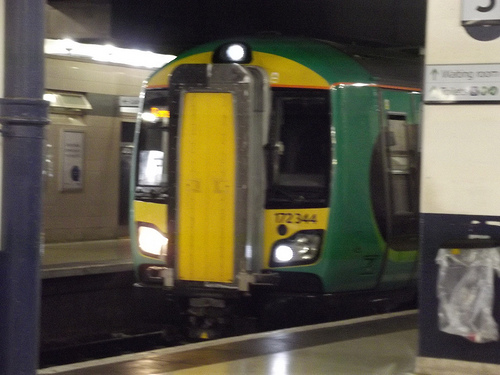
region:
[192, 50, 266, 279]
front yellow door to rain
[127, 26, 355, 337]
yellow and green train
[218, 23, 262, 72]
front light on top of train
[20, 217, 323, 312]
lights on bottom of train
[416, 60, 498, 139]
direction map with arrows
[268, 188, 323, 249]
numbers on bottom of train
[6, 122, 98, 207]
informational poster on wall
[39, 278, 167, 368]
train tracks beneath train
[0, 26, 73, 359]
blue metal pole by train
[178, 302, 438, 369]
platform by train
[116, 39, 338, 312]
front of train car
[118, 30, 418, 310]
green and white train car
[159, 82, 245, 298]
door on the car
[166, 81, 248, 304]
yellow door on the car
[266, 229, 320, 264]
headlight of the train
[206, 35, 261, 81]
top headlight of the train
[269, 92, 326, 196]
windshield of the train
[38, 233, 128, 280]
platform at the train station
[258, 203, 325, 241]
unique number of the car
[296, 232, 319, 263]
headlight in the off status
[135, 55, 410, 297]
subway train on the tracks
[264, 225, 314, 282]
light on the train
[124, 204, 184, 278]
light on the train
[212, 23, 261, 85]
light on the train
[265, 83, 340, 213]
window on the train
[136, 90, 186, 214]
window on the train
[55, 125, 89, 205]
sign on the wall near the train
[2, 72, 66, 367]
post near the train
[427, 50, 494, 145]
sign on the wall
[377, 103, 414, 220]
window on the train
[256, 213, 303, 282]
Light on back of train.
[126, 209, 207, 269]
Light on back of train.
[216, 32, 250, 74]
Light on back of train.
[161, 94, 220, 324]
Yellow door on back of train.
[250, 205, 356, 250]
Black numbers on back of train.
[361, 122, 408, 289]
Ladder on side of train.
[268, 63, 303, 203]
Window on back of train.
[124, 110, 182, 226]
Window on back of train.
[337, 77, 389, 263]
Train is green on side.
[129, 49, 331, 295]
Back of train is yellow.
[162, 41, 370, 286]
green yellow and gray passenger train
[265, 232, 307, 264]
white light on passenger train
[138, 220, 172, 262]
white light on passenger train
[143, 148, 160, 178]
white light on passenger train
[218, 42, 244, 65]
white light on passenger train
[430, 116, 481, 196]
tan wall in train station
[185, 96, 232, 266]
yellow door on passenger train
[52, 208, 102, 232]
tan wall in train station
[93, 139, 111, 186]
tan wall in train station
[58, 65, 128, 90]
tan wall in train station